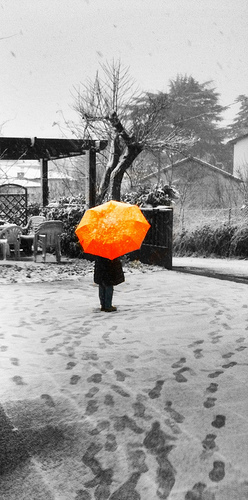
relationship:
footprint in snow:
[198, 452, 238, 490] [198, 442, 246, 489]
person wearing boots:
[89, 254, 126, 314] [103, 303, 117, 308]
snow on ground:
[2, 270, 239, 498] [26, 316, 187, 433]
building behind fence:
[153, 147, 240, 221] [177, 204, 232, 258]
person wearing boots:
[89, 254, 126, 314] [98, 295, 117, 314]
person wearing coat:
[89, 254, 126, 314] [92, 253, 125, 286]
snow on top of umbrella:
[89, 206, 125, 235] [74, 197, 146, 258]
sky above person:
[0, 1, 239, 147] [89, 254, 126, 314]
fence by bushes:
[174, 206, 239, 232] [172, 222, 184, 258]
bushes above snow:
[172, 220, 239, 258] [173, 255, 234, 275]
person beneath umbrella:
[89, 254, 126, 314] [72, 196, 153, 261]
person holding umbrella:
[89, 254, 126, 314] [72, 196, 153, 261]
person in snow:
[89, 254, 126, 314] [2, 270, 239, 498]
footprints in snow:
[46, 301, 183, 497] [2, 267, 239, 419]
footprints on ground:
[46, 301, 183, 497] [1, 256, 239, 498]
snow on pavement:
[2, 270, 239, 498] [0, 269, 246, 498]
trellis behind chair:
[1, 180, 30, 234] [21, 215, 45, 257]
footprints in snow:
[81, 366, 134, 418] [2, 270, 239, 498]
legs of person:
[95, 284, 118, 312] [89, 254, 126, 314]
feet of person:
[98, 304, 116, 310] [89, 254, 126, 314]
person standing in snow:
[89, 254, 126, 314] [2, 270, 239, 498]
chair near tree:
[30, 221, 65, 263] [64, 72, 210, 212]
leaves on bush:
[145, 95, 168, 111] [126, 83, 205, 132]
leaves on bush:
[216, 233, 221, 240] [208, 232, 225, 244]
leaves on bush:
[233, 241, 240, 253] [192, 228, 239, 249]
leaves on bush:
[224, 240, 238, 255] [195, 227, 232, 253]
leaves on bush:
[202, 227, 225, 242] [191, 224, 237, 252]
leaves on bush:
[216, 227, 229, 238] [223, 227, 236, 241]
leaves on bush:
[65, 231, 72, 245] [56, 208, 84, 244]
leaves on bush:
[216, 233, 225, 242] [204, 226, 234, 246]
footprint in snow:
[146, 374, 162, 397] [96, 346, 216, 424]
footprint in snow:
[212, 414, 227, 429] [182, 388, 235, 445]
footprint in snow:
[208, 457, 227, 480] [175, 406, 239, 466]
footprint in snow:
[9, 373, 25, 386] [5, 355, 102, 400]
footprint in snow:
[141, 371, 170, 401] [115, 358, 190, 408]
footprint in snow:
[190, 335, 205, 348] [164, 323, 235, 369]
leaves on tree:
[171, 106, 186, 124] [133, 89, 189, 178]